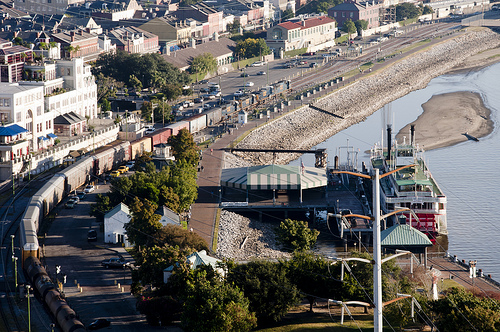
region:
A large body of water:
[278, 46, 498, 283]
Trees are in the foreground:
[107, 124, 276, 330]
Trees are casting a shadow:
[36, 181, 149, 330]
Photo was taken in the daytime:
[2, 1, 497, 315]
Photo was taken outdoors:
[6, 6, 493, 321]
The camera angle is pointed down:
[11, 7, 488, 317]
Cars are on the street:
[188, 55, 310, 107]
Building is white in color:
[3, 57, 98, 152]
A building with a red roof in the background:
[268, 12, 339, 72]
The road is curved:
[33, 158, 134, 329]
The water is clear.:
[447, 154, 498, 266]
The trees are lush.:
[153, 251, 246, 326]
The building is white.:
[10, 71, 50, 138]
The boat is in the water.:
[350, 118, 455, 245]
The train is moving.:
[17, 73, 307, 295]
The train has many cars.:
[15, 88, 321, 299]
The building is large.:
[275, 7, 342, 59]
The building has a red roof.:
[267, 6, 347, 56]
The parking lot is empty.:
[188, 43, 349, 114]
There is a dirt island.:
[390, 72, 498, 186]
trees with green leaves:
[121, 145, 193, 210]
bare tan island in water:
[384, 80, 496, 159]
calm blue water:
[452, 153, 494, 187]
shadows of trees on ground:
[43, 209, 133, 324]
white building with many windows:
[1, 53, 99, 141]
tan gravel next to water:
[270, 117, 333, 147]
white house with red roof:
[269, 13, 349, 60]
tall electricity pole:
[339, 149, 419, 320]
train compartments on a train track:
[53, 153, 121, 188]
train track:
[290, 70, 350, 90]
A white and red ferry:
[378, 123, 454, 248]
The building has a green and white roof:
[220, 145, 340, 207]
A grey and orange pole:
[314, 118, 431, 325]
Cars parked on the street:
[141, 38, 420, 125]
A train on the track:
[25, 66, 294, 243]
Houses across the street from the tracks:
[11, 8, 448, 63]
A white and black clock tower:
[142, 137, 181, 188]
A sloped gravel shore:
[248, 54, 483, 154]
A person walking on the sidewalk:
[201, 144, 214, 156]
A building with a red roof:
[258, 19, 350, 60]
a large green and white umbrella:
[224, 160, 319, 194]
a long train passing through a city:
[78, 146, 117, 168]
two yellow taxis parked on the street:
[111, 168, 128, 169]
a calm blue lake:
[454, 160, 499, 218]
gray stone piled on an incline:
[226, 219, 240, 256]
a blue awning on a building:
[0, 124, 32, 136]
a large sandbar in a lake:
[424, 84, 487, 144]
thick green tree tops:
[188, 274, 246, 326]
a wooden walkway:
[335, 180, 383, 222]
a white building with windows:
[26, 72, 96, 122]